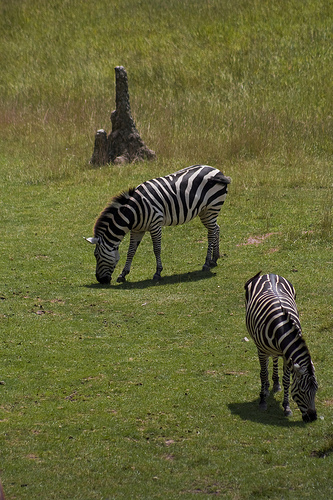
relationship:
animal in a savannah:
[84, 162, 234, 279] [6, 7, 331, 471]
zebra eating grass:
[84, 165, 233, 284] [1, 0, 332, 499]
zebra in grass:
[84, 165, 233, 284] [3, 167, 322, 498]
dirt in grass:
[244, 230, 278, 247] [48, 321, 159, 362]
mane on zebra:
[85, 191, 139, 215] [86, 164, 244, 298]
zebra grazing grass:
[243, 268, 318, 422] [1, 0, 332, 499]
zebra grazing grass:
[84, 165, 233, 284] [1, 0, 332, 499]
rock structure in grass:
[92, 62, 158, 163] [1, 0, 332, 499]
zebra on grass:
[84, 165, 233, 284] [54, 147, 327, 450]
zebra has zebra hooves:
[243, 268, 318, 422] [245, 375, 296, 437]